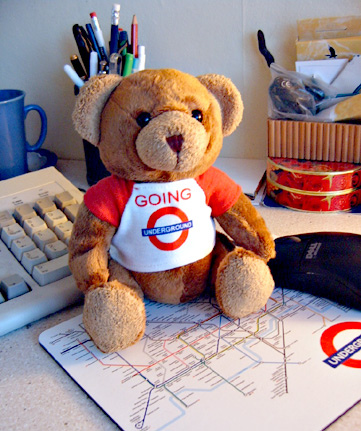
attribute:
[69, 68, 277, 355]
bear — stuffed, teddy bear, toy, brown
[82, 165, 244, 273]
shirt — going underground, tiny, underground, red, white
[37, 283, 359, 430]
mouse pad — white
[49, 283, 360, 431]
map — white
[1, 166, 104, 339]
keyboard — computer keyboard, white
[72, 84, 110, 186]
cup — blue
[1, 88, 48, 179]
cup — blue, coffee cup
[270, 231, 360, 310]
mouse — black, computer mouse, dell brand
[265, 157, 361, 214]
can — red, round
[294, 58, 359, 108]
paper — note paper, white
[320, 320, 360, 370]
logo — red, blue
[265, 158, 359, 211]
roses — red, printed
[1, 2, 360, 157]
wall — white